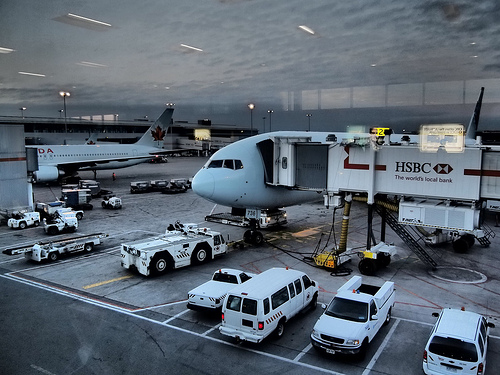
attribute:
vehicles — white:
[185, 263, 499, 373]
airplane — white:
[190, 86, 487, 226]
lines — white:
[280, 346, 305, 374]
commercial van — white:
[221, 266, 316, 338]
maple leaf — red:
[126, 102, 199, 164]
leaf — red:
[148, 122, 165, 143]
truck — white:
[314, 275, 394, 356]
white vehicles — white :
[184, 267, 449, 367]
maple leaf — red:
[149, 123, 165, 138]